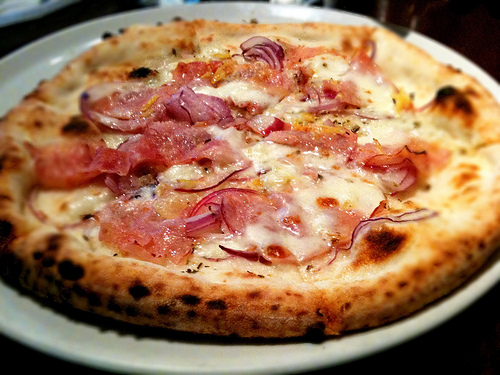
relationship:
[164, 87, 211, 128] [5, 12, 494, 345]
ham on pizza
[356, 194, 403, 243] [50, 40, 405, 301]
onion on pizza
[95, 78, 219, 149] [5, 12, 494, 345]
ham on pizza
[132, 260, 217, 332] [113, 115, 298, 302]
crust on pizza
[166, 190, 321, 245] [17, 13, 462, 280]
cheese on pizza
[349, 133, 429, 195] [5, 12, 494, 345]
ham on pizza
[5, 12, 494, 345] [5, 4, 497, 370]
pizza on plate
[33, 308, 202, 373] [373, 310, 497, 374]
white plate on dark counter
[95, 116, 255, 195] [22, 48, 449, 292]
ham on pizza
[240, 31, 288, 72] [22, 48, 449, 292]
onion clump on pizza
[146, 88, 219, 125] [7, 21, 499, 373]
ham on pizza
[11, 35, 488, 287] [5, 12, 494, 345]
cheese on pizza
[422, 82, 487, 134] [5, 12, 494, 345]
burned cheese on pizza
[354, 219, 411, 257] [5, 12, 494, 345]
burned cheese on pizza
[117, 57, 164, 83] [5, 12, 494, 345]
burned cheese on pizza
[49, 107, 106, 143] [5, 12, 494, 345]
burned cheese on pizza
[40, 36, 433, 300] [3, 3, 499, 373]
pizza on tray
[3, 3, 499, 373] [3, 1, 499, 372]
tray sitting on table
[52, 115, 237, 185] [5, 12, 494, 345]
meat on pizza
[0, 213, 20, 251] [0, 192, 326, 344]
spot on crust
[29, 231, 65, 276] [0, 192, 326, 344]
spot on crust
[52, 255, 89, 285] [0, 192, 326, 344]
spot on crust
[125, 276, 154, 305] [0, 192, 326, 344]
spot on crust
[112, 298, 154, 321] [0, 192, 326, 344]
spot on crust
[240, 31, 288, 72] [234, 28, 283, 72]
onion clump on top of pizza